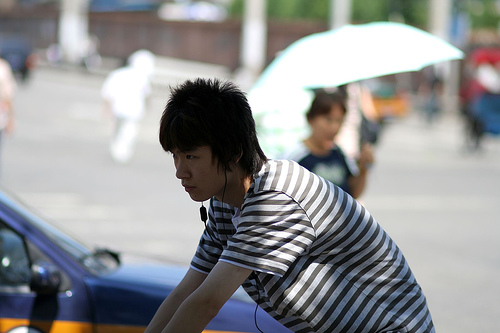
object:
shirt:
[188, 158, 436, 333]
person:
[278, 90, 376, 200]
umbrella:
[244, 21, 468, 97]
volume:
[199, 206, 208, 222]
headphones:
[198, 140, 263, 332]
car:
[0, 195, 289, 330]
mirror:
[29, 258, 63, 294]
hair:
[159, 77, 269, 176]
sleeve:
[216, 192, 315, 278]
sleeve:
[188, 197, 223, 275]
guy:
[142, 76, 435, 332]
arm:
[145, 198, 224, 332]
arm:
[160, 190, 318, 332]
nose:
[175, 158, 190, 179]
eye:
[186, 154, 197, 159]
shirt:
[274, 140, 359, 197]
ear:
[233, 142, 244, 164]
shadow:
[304, 205, 431, 323]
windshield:
[0, 194, 107, 274]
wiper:
[79, 247, 123, 269]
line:
[0, 316, 236, 332]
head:
[156, 76, 269, 202]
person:
[100, 47, 161, 164]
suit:
[98, 68, 155, 162]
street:
[0, 133, 498, 331]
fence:
[0, 0, 358, 76]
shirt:
[101, 66, 150, 117]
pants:
[101, 111, 143, 164]